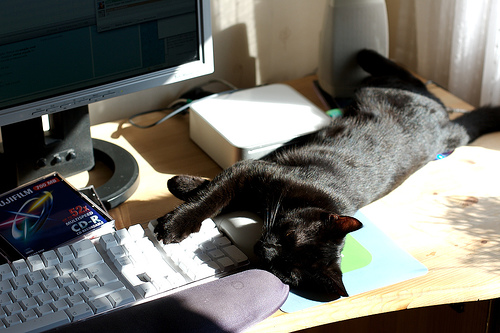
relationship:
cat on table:
[285, 115, 407, 212] [137, 138, 198, 176]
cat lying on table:
[285, 115, 407, 212] [137, 138, 198, 176]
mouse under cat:
[224, 215, 257, 245] [285, 115, 407, 212]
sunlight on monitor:
[181, 61, 217, 75] [11, 10, 205, 82]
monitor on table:
[11, 10, 205, 82] [137, 138, 198, 176]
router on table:
[202, 92, 299, 147] [137, 138, 198, 176]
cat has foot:
[285, 115, 407, 212] [156, 205, 198, 248]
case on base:
[12, 190, 100, 240] [109, 147, 139, 196]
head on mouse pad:
[277, 219, 342, 294] [352, 238, 418, 290]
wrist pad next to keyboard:
[136, 293, 241, 332] [23, 229, 172, 320]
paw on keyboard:
[156, 205, 198, 248] [23, 229, 172, 320]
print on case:
[61, 206, 90, 218] [12, 190, 100, 240]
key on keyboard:
[59, 274, 69, 287] [23, 229, 172, 320]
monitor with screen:
[11, 10, 205, 82] [13, 20, 37, 37]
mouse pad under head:
[352, 238, 418, 290] [277, 219, 342, 294]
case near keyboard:
[12, 190, 100, 240] [23, 229, 172, 320]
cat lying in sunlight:
[285, 115, 407, 212] [376, 194, 458, 250]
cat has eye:
[285, 115, 407, 212] [282, 234, 292, 246]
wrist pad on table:
[136, 293, 241, 332] [137, 138, 198, 176]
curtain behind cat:
[413, 8, 494, 77] [285, 115, 407, 212]